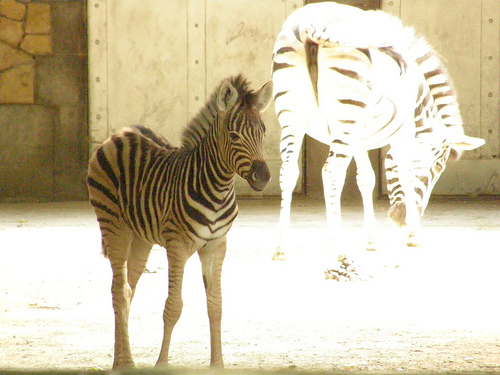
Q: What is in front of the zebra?
A: A door.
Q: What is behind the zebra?
A: Grey and tan wall.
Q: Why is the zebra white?
A: Zebra is in the sunlight.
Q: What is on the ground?
A: Natural light.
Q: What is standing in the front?
A: Zebra.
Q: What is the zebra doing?
A: Grazing.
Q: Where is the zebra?
A: In a pen area.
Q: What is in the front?
A: Young zebra.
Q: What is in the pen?
A: Black and white zebras.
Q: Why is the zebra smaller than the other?
A: Zebra is young.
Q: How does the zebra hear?
A: With ears.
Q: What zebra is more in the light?
A: The back zebra.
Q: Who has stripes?
A: Two zebras.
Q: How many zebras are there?
A: Two.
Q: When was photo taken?
A: Daytime.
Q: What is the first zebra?
A: A baby.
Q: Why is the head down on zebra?
A: Eating.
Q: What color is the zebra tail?
A: Black.